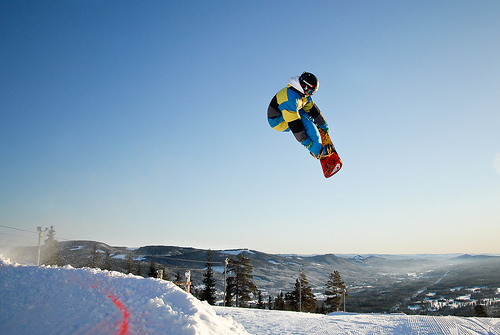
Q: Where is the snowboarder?
A: Airborne.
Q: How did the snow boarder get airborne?
A: By using a snow ramp.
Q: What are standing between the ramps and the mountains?
A: Trees.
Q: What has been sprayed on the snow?
A: Pink paint.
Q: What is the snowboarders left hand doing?
A: Grabbing the snowboard.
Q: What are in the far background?
A: Mountains.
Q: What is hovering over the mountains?
A: A mist.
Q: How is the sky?
A: Cloudless.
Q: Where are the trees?
A: On the side of the hill.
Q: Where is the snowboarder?
A: In the air.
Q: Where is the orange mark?
A: On the snow.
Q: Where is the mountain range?
A: In the distance.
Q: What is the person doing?
A: Snowboarding.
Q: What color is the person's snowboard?
A: Black, red and white.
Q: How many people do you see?
A: 1.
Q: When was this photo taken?
A: During the day.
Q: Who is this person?
A: A snowboarder.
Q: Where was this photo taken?
A: On a hill.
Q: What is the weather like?
A: Clear and cold.